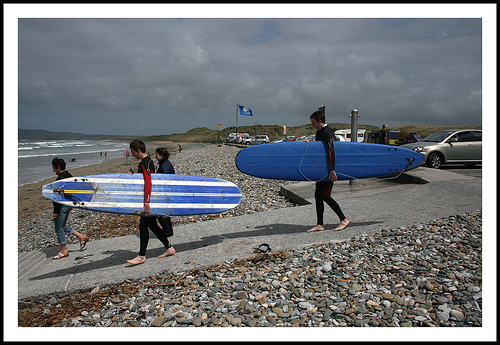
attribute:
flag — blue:
[238, 105, 252, 118]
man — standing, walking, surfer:
[306, 109, 350, 233]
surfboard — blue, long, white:
[235, 138, 428, 180]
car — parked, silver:
[394, 126, 482, 168]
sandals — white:
[51, 236, 89, 260]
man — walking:
[125, 139, 177, 265]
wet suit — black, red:
[133, 158, 172, 254]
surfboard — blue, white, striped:
[39, 170, 244, 217]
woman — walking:
[150, 146, 178, 239]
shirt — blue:
[155, 160, 175, 174]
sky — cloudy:
[20, 19, 481, 138]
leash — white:
[297, 139, 412, 188]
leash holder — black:
[403, 154, 414, 171]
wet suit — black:
[310, 127, 345, 223]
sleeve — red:
[139, 165, 155, 205]